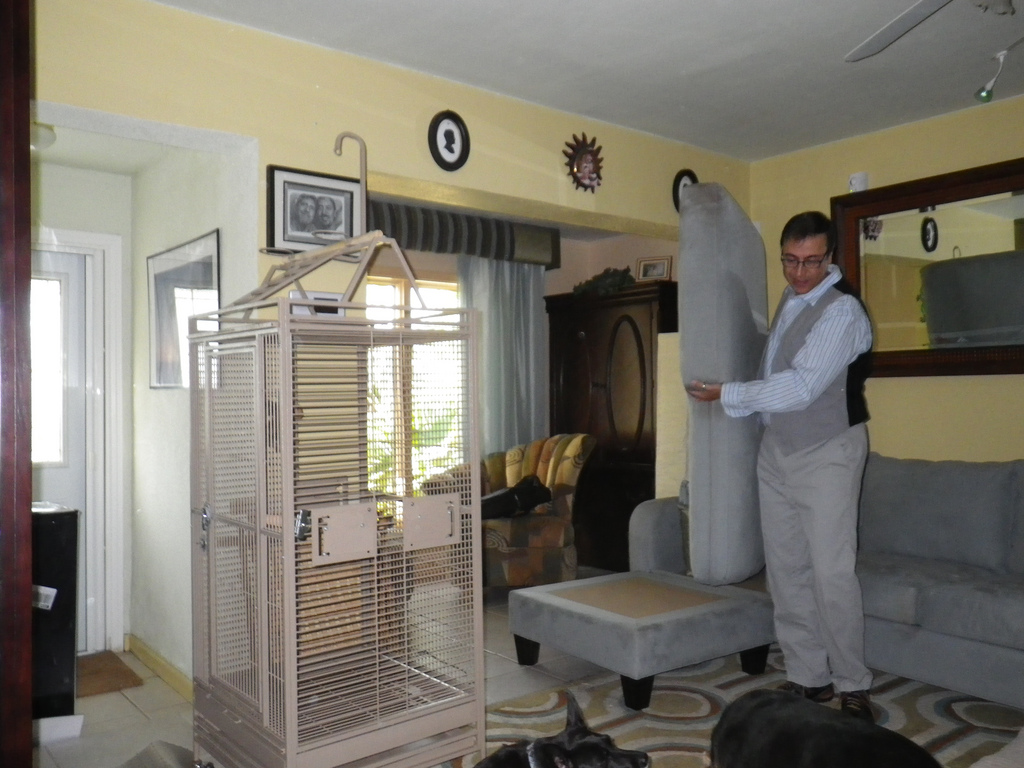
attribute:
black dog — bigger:
[707, 680, 937, 765]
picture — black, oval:
[430, 112, 476, 171]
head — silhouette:
[441, 129, 455, 142]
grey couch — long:
[502, 459, 991, 706]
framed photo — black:
[262, 164, 373, 258]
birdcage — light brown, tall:
[193, 231, 487, 763]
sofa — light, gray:
[497, 451, 984, 709]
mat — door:
[70, 643, 146, 695]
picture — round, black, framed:
[422, 109, 470, 172]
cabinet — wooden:
[541, 271, 676, 580]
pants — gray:
[750, 417, 874, 694]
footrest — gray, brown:
[502, 564, 775, 711]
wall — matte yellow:
[33, 3, 751, 678]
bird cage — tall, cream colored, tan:
[182, 225, 492, 764]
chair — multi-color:
[418, 428, 598, 603]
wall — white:
[134, 134, 256, 698]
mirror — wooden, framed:
[826, 156, 993, 377]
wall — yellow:
[748, 91, 993, 463]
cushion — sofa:
[673, 178, 771, 589]